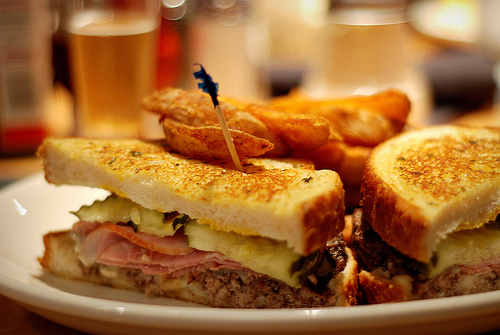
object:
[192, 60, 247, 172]
toothpick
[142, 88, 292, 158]
french fries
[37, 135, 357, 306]
bread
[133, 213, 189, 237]
pickles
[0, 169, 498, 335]
plate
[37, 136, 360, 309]
sandwich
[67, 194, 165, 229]
pickle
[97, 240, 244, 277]
meat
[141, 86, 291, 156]
fries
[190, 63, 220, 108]
plastic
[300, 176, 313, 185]
pepper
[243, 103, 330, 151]
french fries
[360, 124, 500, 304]
sandwich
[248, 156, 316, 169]
fries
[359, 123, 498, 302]
bread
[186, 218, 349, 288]
pickle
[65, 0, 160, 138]
glass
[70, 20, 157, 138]
beer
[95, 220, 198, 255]
meat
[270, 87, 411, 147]
french fry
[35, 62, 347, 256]
wedge